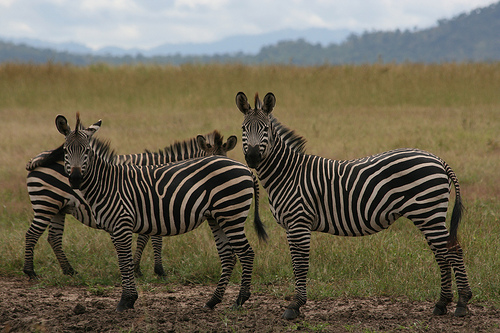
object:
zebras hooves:
[231, 289, 253, 306]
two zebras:
[20, 112, 269, 316]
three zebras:
[18, 90, 474, 320]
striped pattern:
[362, 152, 423, 223]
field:
[0, 59, 499, 332]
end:
[408, 147, 451, 211]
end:
[214, 158, 259, 213]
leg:
[217, 217, 259, 295]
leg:
[205, 214, 237, 300]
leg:
[444, 224, 474, 304]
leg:
[403, 211, 458, 304]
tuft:
[250, 216, 269, 247]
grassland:
[0, 58, 499, 312]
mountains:
[0, 0, 499, 64]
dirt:
[0, 276, 498, 333]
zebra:
[231, 90, 473, 321]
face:
[240, 114, 274, 170]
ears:
[232, 91, 253, 114]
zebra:
[53, 114, 272, 313]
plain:
[0, 58, 498, 332]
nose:
[241, 146, 264, 170]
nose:
[67, 165, 85, 192]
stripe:
[171, 159, 241, 237]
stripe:
[150, 182, 164, 240]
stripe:
[180, 166, 254, 235]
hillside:
[0, 0, 499, 61]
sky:
[0, 0, 499, 56]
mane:
[85, 134, 117, 163]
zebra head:
[194, 129, 238, 160]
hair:
[210, 128, 227, 150]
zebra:
[20, 130, 237, 282]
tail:
[247, 170, 270, 244]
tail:
[436, 159, 470, 245]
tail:
[20, 143, 67, 173]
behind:
[20, 153, 52, 216]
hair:
[270, 115, 308, 155]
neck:
[253, 122, 287, 186]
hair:
[73, 109, 82, 136]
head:
[53, 109, 105, 192]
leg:
[279, 213, 313, 307]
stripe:
[366, 164, 450, 223]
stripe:
[412, 187, 451, 202]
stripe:
[156, 154, 207, 197]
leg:
[109, 232, 139, 302]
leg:
[148, 235, 164, 272]